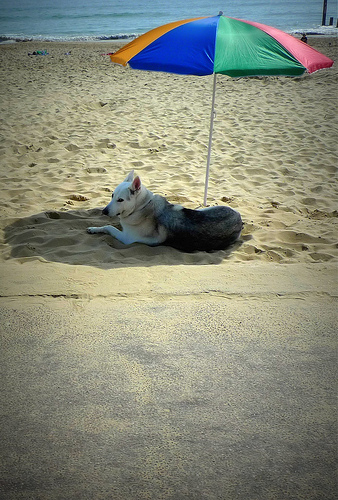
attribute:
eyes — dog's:
[108, 187, 122, 205]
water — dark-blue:
[2, 1, 337, 38]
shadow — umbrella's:
[8, 177, 93, 271]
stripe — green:
[216, 12, 303, 80]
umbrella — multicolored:
[108, 11, 336, 207]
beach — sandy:
[0, 39, 335, 297]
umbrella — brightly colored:
[110, 14, 329, 73]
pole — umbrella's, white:
[203, 72, 217, 198]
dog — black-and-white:
[87, 167, 244, 254]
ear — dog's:
[125, 174, 141, 191]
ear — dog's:
[122, 168, 133, 182]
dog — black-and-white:
[79, 167, 249, 265]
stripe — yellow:
[110, 16, 196, 68]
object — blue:
[27, 49, 50, 55]